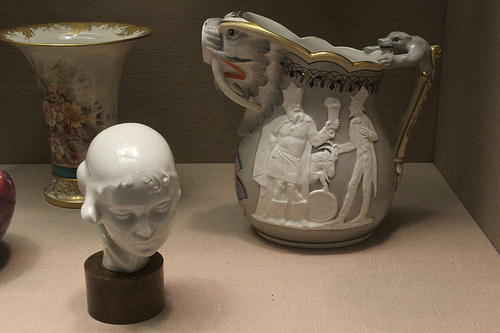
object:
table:
[270, 289, 371, 309]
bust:
[76, 122, 181, 325]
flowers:
[42, 84, 71, 127]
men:
[251, 81, 342, 228]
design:
[251, 81, 379, 231]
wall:
[456, 50, 484, 102]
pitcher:
[249, 81, 378, 231]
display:
[0, 233, 500, 333]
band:
[52, 165, 77, 179]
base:
[82, 249, 165, 325]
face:
[101, 195, 181, 258]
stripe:
[51, 160, 77, 179]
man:
[252, 82, 342, 228]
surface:
[238, 73, 395, 244]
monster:
[363, 31, 433, 75]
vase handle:
[377, 31, 443, 189]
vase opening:
[0, 20, 152, 48]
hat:
[350, 86, 370, 113]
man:
[324, 86, 380, 226]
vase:
[201, 10, 443, 249]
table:
[452, 270, 500, 330]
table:
[0, 244, 72, 326]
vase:
[0, 21, 154, 209]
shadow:
[186, 202, 281, 254]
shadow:
[351, 203, 447, 253]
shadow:
[0, 231, 43, 285]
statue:
[75, 122, 180, 275]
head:
[75, 122, 180, 273]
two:
[252, 82, 379, 232]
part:
[0, 170, 18, 269]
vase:
[0, 170, 16, 268]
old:
[66, 99, 96, 131]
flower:
[64, 65, 79, 76]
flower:
[60, 152, 76, 162]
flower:
[37, 71, 45, 80]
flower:
[69, 99, 85, 108]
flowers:
[73, 102, 102, 142]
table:
[180, 166, 236, 191]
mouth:
[130, 236, 161, 251]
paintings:
[23, 54, 121, 166]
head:
[201, 9, 301, 119]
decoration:
[279, 61, 384, 95]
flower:
[40, 91, 55, 103]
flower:
[41, 65, 47, 75]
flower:
[80, 128, 90, 134]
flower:
[62, 132, 75, 141]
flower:
[98, 111, 110, 120]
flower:
[54, 157, 60, 164]